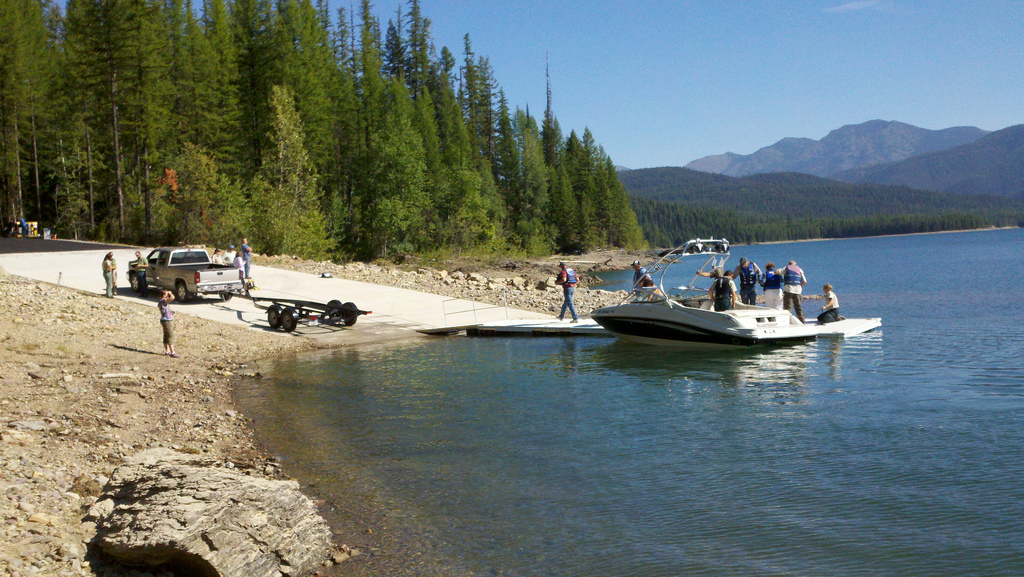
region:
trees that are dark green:
[70, 65, 625, 265]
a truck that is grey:
[127, 222, 242, 309]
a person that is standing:
[71, 241, 136, 296]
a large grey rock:
[70, 420, 277, 566]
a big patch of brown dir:
[45, 331, 181, 436]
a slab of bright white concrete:
[361, 292, 448, 324]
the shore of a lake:
[228, 372, 396, 493]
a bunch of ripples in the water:
[517, 377, 783, 523]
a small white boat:
[634, 271, 815, 357]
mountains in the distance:
[724, 83, 952, 236]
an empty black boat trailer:
[245, 288, 386, 350]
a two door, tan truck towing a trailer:
[108, 233, 252, 310]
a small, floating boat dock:
[442, 247, 883, 353]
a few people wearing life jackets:
[716, 246, 818, 323]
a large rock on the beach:
[91, 424, 342, 573]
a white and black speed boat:
[582, 221, 820, 370]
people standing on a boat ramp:
[201, 236, 269, 295]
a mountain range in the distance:
[679, 79, 1022, 200]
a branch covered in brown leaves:
[155, 155, 187, 213]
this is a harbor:
[35, 48, 971, 568]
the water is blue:
[465, 344, 865, 563]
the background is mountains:
[658, 95, 924, 206]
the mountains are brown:
[775, 101, 1011, 311]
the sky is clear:
[620, 57, 766, 144]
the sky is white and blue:
[631, 28, 791, 112]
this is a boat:
[567, 198, 818, 358]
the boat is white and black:
[602, 212, 909, 448]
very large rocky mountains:
[608, 109, 1019, 234]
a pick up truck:
[124, 236, 242, 298]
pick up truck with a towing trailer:
[124, 238, 359, 338]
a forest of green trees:
[1, 26, 649, 262]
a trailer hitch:
[231, 285, 368, 336]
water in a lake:
[326, 241, 1016, 568]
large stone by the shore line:
[96, 435, 337, 566]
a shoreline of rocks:
[5, 282, 268, 574]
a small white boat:
[591, 236, 898, 357]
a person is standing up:
[103, 248, 117, 296]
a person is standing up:
[152, 285, 179, 352]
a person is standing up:
[229, 238, 258, 286]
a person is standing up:
[544, 250, 577, 320]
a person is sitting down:
[800, 282, 842, 321]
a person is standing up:
[751, 258, 781, 313]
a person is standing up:
[710, 263, 742, 308]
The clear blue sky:
[347, 0, 1021, 199]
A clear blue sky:
[350, 9, 1021, 205]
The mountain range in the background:
[630, 107, 1022, 244]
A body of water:
[270, 224, 1021, 573]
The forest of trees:
[8, 0, 612, 272]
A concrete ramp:
[6, 221, 614, 402]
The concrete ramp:
[14, 226, 596, 373]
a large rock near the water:
[73, 431, 349, 575]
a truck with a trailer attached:
[122, 239, 372, 345]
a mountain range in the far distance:
[614, 107, 1007, 184]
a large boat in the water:
[586, 293, 897, 352]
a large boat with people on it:
[580, 254, 890, 362]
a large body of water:
[229, 214, 1017, 569]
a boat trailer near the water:
[219, 283, 379, 340]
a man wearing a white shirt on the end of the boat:
[807, 277, 850, 331]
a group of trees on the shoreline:
[5, 1, 654, 265]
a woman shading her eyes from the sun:
[144, 283, 198, 356]